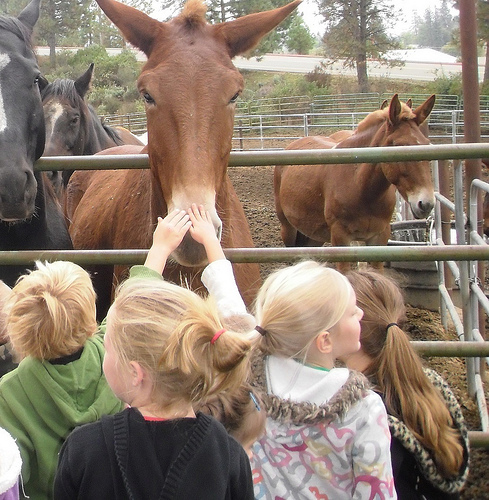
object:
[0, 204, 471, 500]
children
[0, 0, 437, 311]
animals